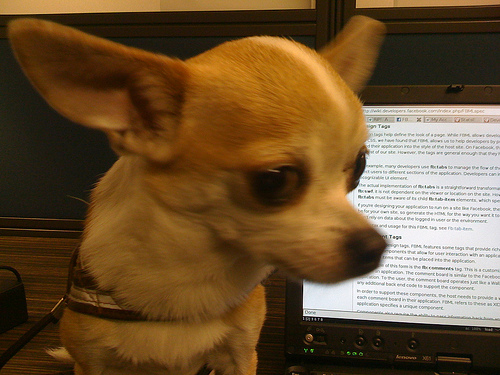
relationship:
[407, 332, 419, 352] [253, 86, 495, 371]
button on laptop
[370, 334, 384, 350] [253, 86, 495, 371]
button on laptop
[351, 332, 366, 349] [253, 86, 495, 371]
button on laptop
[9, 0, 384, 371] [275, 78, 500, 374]
dog in front of laptop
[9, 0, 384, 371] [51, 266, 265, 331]
dog with collar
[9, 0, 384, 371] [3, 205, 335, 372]
dog on floor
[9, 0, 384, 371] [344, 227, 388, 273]
dog with nose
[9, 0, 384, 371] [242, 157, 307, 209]
dog has eye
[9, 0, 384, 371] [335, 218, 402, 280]
dog has nose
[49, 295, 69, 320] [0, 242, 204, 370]
silver spot on leash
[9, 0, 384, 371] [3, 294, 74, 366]
dog has leash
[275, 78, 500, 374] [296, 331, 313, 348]
laptop has button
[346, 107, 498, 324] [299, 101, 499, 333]
words on laptop screen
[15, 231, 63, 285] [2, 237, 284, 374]
carpet on floor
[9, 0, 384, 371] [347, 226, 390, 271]
dog has nose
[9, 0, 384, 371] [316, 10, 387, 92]
dog has ear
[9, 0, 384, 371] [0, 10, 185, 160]
dog has ear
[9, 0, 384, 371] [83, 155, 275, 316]
dog has neck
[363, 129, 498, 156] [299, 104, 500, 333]
writing on laptop screen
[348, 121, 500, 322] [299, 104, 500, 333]
writing on laptop screen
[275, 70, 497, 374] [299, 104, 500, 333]
laptop has laptop screen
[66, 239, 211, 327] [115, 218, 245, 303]
collar on neck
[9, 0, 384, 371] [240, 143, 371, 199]
dog has eyes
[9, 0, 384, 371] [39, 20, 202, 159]
dog has ears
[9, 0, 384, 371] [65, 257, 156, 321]
dog has collar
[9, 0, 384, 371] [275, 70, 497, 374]
dog beside laptop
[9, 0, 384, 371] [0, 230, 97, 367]
dog on table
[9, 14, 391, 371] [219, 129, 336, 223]
dog has eye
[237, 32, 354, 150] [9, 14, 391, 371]
stripe on dog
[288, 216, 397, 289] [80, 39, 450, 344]
nose on dog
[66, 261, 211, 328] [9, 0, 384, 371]
collar on dog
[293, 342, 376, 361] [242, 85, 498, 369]
lights on computer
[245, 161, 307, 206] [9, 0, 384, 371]
eye on dog